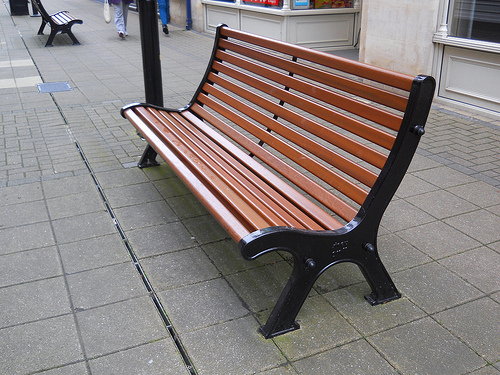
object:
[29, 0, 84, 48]
benches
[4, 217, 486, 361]
sidewalk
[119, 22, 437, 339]
bench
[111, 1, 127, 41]
person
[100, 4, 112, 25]
bag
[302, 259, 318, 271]
bolt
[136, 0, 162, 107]
pole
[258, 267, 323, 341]
leg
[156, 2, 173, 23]
jean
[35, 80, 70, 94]
drain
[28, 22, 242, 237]
sidewalk